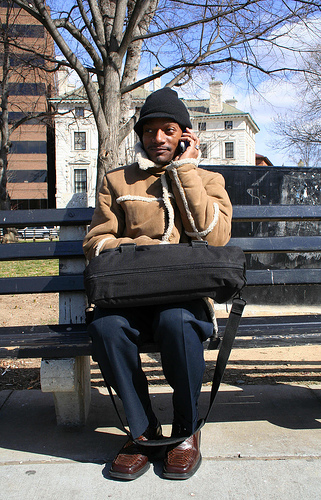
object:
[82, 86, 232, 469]
man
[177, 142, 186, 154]
cellphone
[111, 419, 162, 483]
shoes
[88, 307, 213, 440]
pants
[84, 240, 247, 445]
bag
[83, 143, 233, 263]
jacket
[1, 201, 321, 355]
bench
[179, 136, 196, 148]
finger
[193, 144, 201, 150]
ring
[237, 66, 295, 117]
clouds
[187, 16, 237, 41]
sky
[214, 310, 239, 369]
strap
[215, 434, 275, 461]
ground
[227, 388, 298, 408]
shadows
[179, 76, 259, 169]
building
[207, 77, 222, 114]
chimney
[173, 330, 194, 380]
crease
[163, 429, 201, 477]
dress shoe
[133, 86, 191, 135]
cap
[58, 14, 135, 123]
tree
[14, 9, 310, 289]
winter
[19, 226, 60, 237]
car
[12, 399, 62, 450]
shadow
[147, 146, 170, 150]
mustache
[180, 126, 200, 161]
hand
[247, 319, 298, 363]
sidewalk